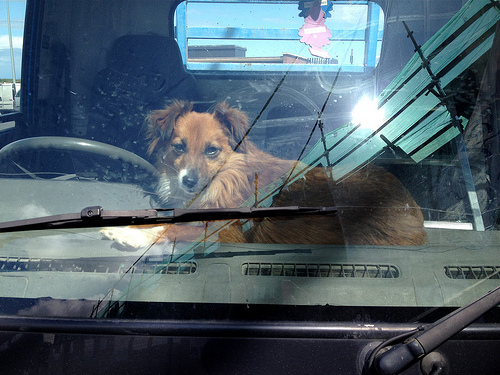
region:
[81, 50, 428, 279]
The dog is brown.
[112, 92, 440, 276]
The dog is laying in the car.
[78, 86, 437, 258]
One dog in the car.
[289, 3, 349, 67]
Red air freshener.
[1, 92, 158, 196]
Steering wheel is grey.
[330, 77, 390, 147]
Sun reflection in the glass.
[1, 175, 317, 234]
Whippers are black.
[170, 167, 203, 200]
Dogs nose is black.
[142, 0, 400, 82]
Fence is blue.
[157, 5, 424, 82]
The fence is made with wood.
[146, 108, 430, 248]
this is a dog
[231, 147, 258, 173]
the fur is brown in color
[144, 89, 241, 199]
this is the dog's head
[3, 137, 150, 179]
this is the steering wheel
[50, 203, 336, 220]
this is a window wiper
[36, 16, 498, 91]
this is the windscreen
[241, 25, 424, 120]
the windscreen is made of glass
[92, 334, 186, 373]
the car is black in color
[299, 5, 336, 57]
this is a car air freshner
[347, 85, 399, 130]
the reflection of the sun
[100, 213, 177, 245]
The paw is white.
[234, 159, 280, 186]
The dog is brown.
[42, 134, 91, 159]
The steering wheel is grey.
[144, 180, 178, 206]
White on the dog's chest.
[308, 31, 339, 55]
Air freshener on the mirror.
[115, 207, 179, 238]
The windshield wiper metal.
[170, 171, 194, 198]
White on the dog's nose.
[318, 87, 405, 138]
Sun shining on the window.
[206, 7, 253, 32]
The sky is blue.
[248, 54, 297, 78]
Wooden object in the bed of the truck.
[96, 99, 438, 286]
brown dog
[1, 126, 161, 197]
steering wheel of the car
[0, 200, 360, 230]
left windshield wiper in the front glass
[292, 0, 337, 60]
air freshener with tree shape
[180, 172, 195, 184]
black nose of the brown dog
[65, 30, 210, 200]
driver's seat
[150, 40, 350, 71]
top of buildings on the rear glass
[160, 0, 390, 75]
rear glass of the car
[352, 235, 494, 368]
windshield wiper at the right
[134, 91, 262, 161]
furry ears of the dog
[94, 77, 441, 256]
a dog sitting on dashboard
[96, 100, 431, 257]
a brown and white dog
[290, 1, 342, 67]
two air fresheners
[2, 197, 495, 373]
two black windshield wipers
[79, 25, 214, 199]
a black driver's seat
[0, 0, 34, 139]
driver's side window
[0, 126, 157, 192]
a gray steering wheel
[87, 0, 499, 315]
a reflection shown in the windshield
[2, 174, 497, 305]
a gray dashboard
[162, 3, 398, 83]
back window